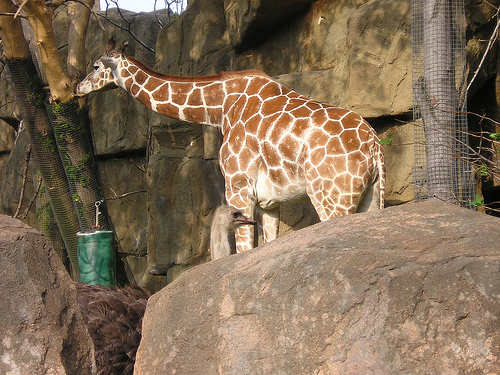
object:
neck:
[115, 61, 231, 131]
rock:
[143, 156, 221, 279]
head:
[72, 35, 133, 99]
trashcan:
[75, 230, 117, 289]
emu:
[70, 204, 255, 375]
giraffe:
[72, 35, 389, 255]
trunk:
[0, 0, 84, 282]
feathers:
[72, 279, 151, 375]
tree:
[14, 1, 131, 287]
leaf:
[475, 193, 483, 202]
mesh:
[410, 0, 479, 209]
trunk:
[11, 0, 131, 289]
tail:
[376, 144, 386, 209]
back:
[220, 68, 373, 129]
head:
[210, 203, 255, 228]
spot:
[134, 70, 148, 85]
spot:
[169, 82, 194, 106]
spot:
[268, 112, 295, 147]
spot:
[339, 129, 362, 154]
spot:
[322, 119, 344, 136]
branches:
[394, 117, 497, 165]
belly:
[257, 167, 307, 210]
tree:
[92, 2, 195, 53]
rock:
[219, 0, 311, 54]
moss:
[35, 103, 96, 234]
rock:
[271, 0, 462, 123]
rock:
[0, 213, 98, 375]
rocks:
[130, 198, 500, 375]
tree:
[412, 1, 464, 205]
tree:
[0, 0, 78, 276]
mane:
[125, 55, 276, 83]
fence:
[409, 0, 478, 210]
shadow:
[254, 8, 315, 76]